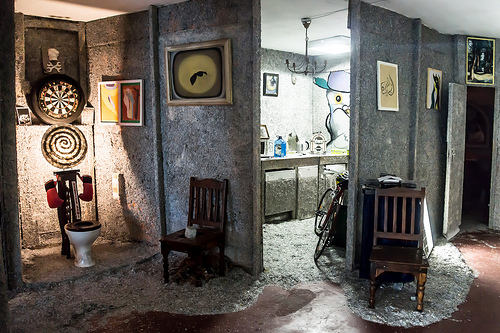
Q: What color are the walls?
A: The walls are grey.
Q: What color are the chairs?
A: The chairs are brown.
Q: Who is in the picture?
A: Nobody is in the picture.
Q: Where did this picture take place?
A: It took place in a house.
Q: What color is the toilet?
A: The toilet is white.